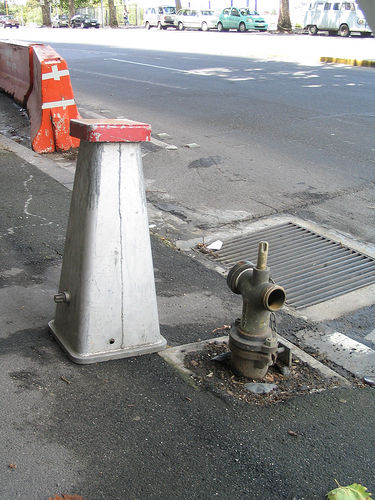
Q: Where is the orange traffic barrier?
A: On the side of the road.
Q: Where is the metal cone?
A: On the sidewalk.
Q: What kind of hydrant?
A: Water.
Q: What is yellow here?
A: The curb.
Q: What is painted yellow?
A: The curb.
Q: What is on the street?
A: A grate.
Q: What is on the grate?
A: Paper.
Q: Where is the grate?
A: On the street.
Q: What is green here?
A: The car.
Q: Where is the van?
A: In the parking lot.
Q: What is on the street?
A: A white line.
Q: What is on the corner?
A: A grate.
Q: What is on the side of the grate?
A: A metal cone.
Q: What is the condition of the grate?
A: It is rusted.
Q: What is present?
A: A road.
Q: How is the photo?
A: Clear.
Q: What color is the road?
A: Grey.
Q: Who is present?
A: Nobody.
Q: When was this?
A: Daytime.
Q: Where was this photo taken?
A: On the street.